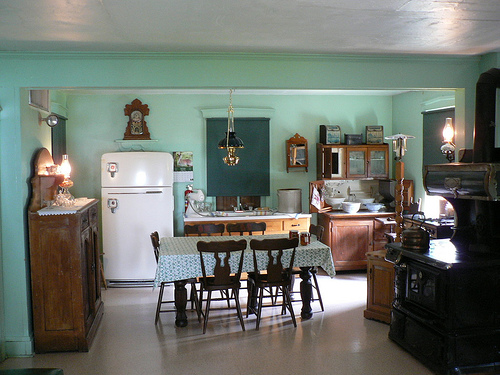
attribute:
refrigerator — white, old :
[97, 150, 177, 290]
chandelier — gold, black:
[215, 87, 249, 168]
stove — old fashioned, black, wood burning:
[386, 79, 498, 349]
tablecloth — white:
[155, 232, 336, 282]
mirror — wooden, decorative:
[283, 127, 310, 172]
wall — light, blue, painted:
[7, 46, 474, 350]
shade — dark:
[209, 116, 276, 201]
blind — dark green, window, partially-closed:
[183, 100, 290, 196]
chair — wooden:
[151, 233, 206, 326]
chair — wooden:
[183, 224, 225, 299]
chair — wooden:
[226, 221, 266, 297]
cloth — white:
[153, 233, 338, 278]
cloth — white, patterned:
[153, 232, 342, 283]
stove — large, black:
[381, 62, 498, 374]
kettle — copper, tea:
[399, 210, 430, 250]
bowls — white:
[330, 189, 388, 225]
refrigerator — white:
[88, 133, 193, 306]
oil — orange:
[58, 177, 75, 188]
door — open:
[323, 146, 330, 177]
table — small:
[156, 232, 331, 320]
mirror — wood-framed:
[284, 137, 309, 172]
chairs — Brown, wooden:
[189, 237, 306, 332]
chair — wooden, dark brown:
[246, 237, 298, 329]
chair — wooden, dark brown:
[196, 240, 247, 335]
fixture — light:
[209, 100, 249, 170]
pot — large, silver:
[275, 185, 305, 212]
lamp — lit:
[430, 113, 454, 156]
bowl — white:
[341, 201, 362, 216]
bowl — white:
[365, 201, 380, 211]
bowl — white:
[322, 197, 346, 209]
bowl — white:
[358, 196, 373, 208]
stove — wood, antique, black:
[382, 162, 497, 370]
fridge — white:
[84, 159, 206, 292]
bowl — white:
[342, 196, 363, 216]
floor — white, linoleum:
[0, 271, 432, 373]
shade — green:
[205, 120, 269, 197]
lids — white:
[291, 223, 305, 234]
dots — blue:
[155, 235, 334, 289]